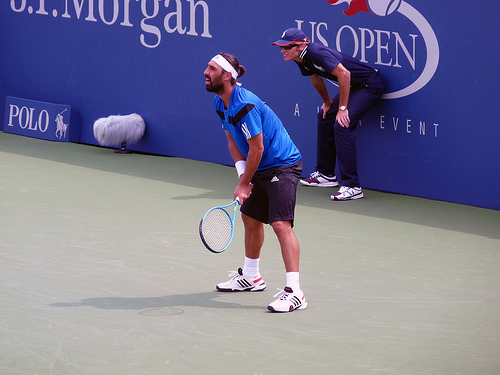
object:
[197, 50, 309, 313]
man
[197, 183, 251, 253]
tennis racket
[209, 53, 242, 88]
headband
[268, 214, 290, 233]
knees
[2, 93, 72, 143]
ad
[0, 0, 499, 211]
wall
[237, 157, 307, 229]
black shorts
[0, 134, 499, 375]
tennis court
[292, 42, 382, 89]
blue shirt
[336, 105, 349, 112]
watch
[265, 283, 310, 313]
white shoes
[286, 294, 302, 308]
stripes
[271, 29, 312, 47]
hat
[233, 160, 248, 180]
wristband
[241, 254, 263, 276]
sock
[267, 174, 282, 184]
emblem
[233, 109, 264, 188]
arm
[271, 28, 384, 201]
boy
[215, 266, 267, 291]
right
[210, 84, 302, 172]
shirt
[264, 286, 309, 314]
left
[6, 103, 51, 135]
polo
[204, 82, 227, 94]
beard